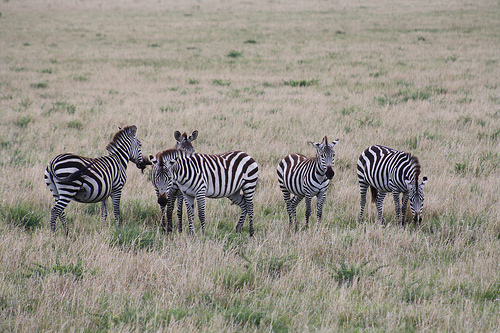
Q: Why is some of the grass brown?
A: It's dry.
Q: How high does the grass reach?
A: To the zebras' knees.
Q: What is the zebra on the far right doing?
A: Eating grass.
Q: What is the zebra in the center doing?
A: Turning toward the zebra on the left.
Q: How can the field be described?
A: Full of brown and green grass.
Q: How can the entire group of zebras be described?
A: A group of standing zebras.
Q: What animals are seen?
A: ZEBRAS.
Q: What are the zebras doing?
A: Grazing.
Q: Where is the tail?
A: On the zebra's butt.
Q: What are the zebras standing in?
A: Grass.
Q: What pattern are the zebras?
A: Striped.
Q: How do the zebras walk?
A: With their legs.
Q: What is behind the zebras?
A: Grass.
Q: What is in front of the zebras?
A: Grass.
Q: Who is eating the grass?
A: Zebras.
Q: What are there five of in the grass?
A: Zebra.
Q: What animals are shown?
A: Zebras.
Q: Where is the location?
A: The wild.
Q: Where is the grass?
A: On the ground.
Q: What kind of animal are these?
A: Zebras.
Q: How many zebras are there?
A: Five.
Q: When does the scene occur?
A: Daytime.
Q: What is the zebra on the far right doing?
A: Eating grass.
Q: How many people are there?
A: None.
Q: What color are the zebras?
A: Black and white.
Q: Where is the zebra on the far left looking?
A: Away from the camera.